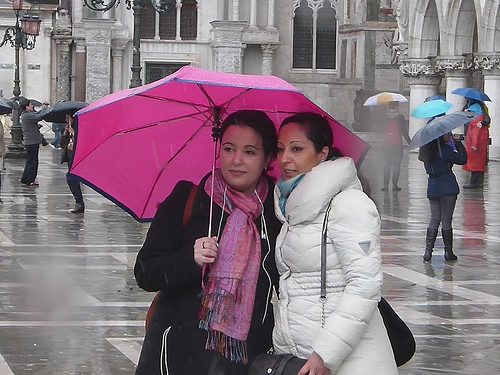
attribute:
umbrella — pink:
[67, 63, 374, 225]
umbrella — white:
[363, 92, 409, 106]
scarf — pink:
[201, 171, 269, 363]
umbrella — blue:
[409, 113, 476, 149]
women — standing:
[132, 110, 396, 375]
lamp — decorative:
[1, 1, 42, 159]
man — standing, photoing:
[17, 99, 50, 187]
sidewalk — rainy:
[4, 220, 103, 373]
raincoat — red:
[465, 116, 489, 172]